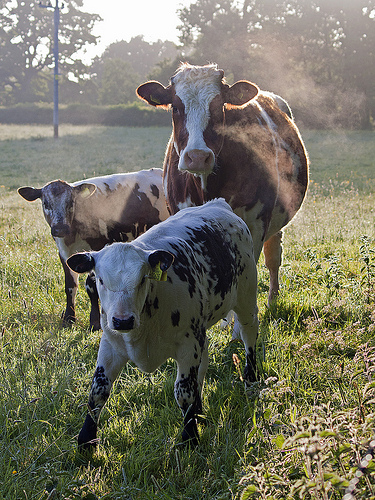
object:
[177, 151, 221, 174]
nose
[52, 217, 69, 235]
nose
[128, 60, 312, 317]
cow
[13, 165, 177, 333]
cow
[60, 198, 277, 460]
cow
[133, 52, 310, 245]
cow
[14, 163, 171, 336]
cow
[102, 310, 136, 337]
nose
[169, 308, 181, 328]
spot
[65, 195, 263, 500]
cow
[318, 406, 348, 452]
wildflowers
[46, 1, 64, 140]
pole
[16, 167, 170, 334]
cow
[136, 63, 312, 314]
cow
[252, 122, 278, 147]
ground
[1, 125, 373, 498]
field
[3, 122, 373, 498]
grass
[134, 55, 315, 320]
cow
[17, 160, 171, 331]
cow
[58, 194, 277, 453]
cow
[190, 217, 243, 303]
spot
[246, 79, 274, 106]
ground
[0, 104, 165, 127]
wall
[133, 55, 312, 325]
cows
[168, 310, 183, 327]
blackspot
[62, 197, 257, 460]
calves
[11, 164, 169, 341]
cow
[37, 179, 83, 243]
face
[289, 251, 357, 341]
grass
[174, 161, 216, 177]
cow's mouth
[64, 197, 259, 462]
cow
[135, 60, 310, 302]
cow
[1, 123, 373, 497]
grassy field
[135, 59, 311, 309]
cow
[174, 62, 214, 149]
white marking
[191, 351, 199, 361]
spot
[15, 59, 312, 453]
group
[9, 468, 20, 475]
flower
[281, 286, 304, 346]
weeds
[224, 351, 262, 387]
flowers